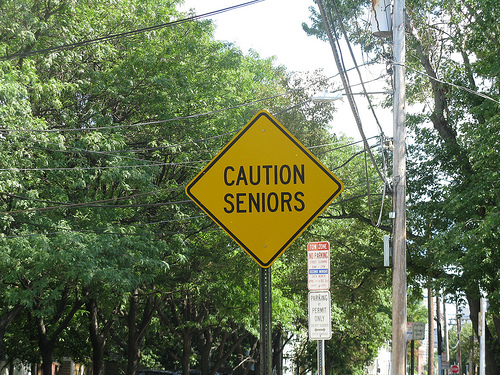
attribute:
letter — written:
[221, 152, 240, 190]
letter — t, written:
[246, 165, 264, 186]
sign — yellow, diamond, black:
[204, 98, 328, 246]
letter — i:
[255, 158, 286, 185]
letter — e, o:
[222, 163, 291, 222]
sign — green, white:
[295, 231, 348, 343]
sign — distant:
[437, 352, 472, 374]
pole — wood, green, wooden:
[371, 36, 426, 347]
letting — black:
[186, 123, 366, 216]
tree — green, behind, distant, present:
[36, 57, 198, 332]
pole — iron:
[238, 265, 291, 362]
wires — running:
[28, 30, 208, 198]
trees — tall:
[435, 31, 495, 281]